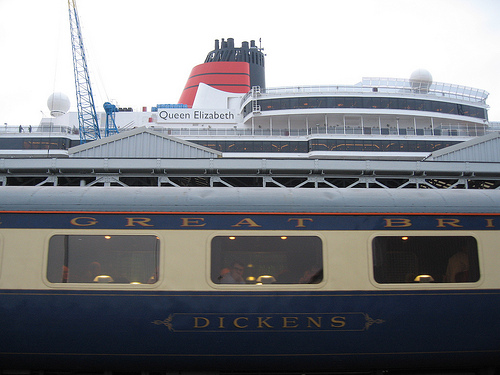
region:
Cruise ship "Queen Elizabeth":
[3, 0, 498, 157]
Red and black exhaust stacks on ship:
[177, 35, 267, 107]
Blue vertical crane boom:
[65, 0, 102, 143]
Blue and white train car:
[1, 185, 498, 370]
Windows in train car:
[43, 232, 485, 288]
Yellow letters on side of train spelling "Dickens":
[148, 308, 388, 333]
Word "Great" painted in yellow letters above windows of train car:
[69, 213, 314, 232]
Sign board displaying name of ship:
[156, 107, 244, 124]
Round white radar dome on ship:
[45, 90, 70, 117]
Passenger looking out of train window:
[218, 257, 247, 282]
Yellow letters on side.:
[157, 310, 384, 335]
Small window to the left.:
[46, 228, 167, 283]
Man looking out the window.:
[223, 258, 258, 288]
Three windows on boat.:
[33, 227, 489, 287]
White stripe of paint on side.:
[0, 223, 497, 294]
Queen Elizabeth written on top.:
[158, 109, 238, 126]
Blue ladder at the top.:
[99, 95, 123, 139]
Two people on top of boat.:
[14, 120, 32, 135]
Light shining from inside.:
[394, 235, 412, 247]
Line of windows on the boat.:
[277, 120, 485, 135]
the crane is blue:
[69, 37, 114, 157]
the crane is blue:
[55, 10, 137, 157]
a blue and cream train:
[13, 172, 418, 362]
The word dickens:
[189, 314, 353, 331]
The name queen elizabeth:
[162, 111, 242, 123]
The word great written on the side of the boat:
[76, 212, 308, 231]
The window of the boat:
[50, 234, 151, 281]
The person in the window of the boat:
[215, 258, 250, 284]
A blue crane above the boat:
[63, 2, 100, 142]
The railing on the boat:
[189, 124, 492, 137]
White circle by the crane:
[40, 92, 73, 112]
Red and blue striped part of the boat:
[196, 62, 249, 90]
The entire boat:
[9, 37, 486, 363]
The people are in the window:
[193, 230, 338, 292]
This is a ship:
[7, 70, 491, 364]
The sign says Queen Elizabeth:
[142, 98, 246, 128]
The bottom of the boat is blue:
[54, 296, 161, 371]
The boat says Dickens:
[166, 299, 393, 356]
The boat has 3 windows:
[25, 225, 495, 294]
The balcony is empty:
[201, 94, 484, 161]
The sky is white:
[106, 39, 210, 124]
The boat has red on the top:
[177, 49, 264, 117]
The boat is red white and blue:
[41, 150, 388, 367]